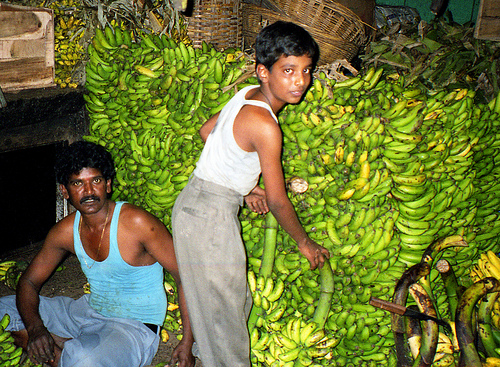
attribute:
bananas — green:
[379, 91, 429, 288]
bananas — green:
[360, 157, 402, 288]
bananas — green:
[331, 108, 396, 358]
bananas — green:
[320, 183, 370, 365]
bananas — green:
[385, 100, 445, 272]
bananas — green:
[357, 180, 413, 365]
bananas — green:
[352, 183, 406, 364]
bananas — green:
[326, 66, 406, 332]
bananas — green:
[297, 96, 436, 352]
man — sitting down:
[20, 95, 205, 365]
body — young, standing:
[136, 6, 315, 364]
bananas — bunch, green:
[331, 56, 492, 176]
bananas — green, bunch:
[314, 68, 497, 221]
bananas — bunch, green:
[312, 87, 480, 257]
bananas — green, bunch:
[338, 33, 498, 252]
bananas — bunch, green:
[312, 66, 483, 236]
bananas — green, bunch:
[322, 52, 497, 258]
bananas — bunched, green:
[342, 80, 496, 230]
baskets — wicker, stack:
[253, 0, 399, 97]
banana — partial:
[289, 310, 337, 355]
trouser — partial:
[240, 279, 264, 316]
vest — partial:
[126, 265, 158, 308]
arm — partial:
[163, 299, 201, 341]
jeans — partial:
[101, 319, 145, 364]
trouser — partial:
[205, 283, 255, 348]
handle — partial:
[355, 274, 430, 334]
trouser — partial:
[192, 266, 286, 364]